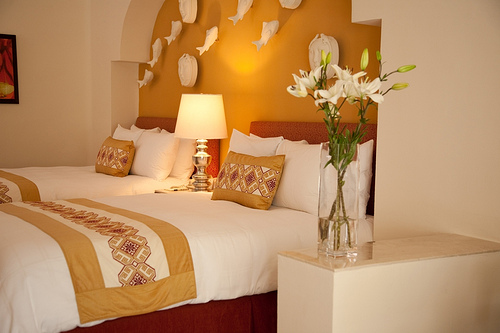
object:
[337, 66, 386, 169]
lillies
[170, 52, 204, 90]
masks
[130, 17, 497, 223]
wall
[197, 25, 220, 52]
fish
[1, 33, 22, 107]
painting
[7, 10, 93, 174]
wall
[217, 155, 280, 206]
pillow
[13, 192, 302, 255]
comforter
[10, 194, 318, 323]
bed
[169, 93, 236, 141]
lamp shade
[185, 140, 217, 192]
base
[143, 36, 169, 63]
art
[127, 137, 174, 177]
pillows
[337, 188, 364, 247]
stems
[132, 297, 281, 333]
bed curtain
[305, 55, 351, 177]
flowers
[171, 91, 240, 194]
lamp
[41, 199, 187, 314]
border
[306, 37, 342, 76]
alcove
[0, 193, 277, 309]
bedsheets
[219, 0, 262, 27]
fishes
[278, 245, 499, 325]
table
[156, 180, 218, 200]
table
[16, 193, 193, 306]
blanket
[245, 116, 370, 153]
headboard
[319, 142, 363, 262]
vase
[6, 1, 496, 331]
room